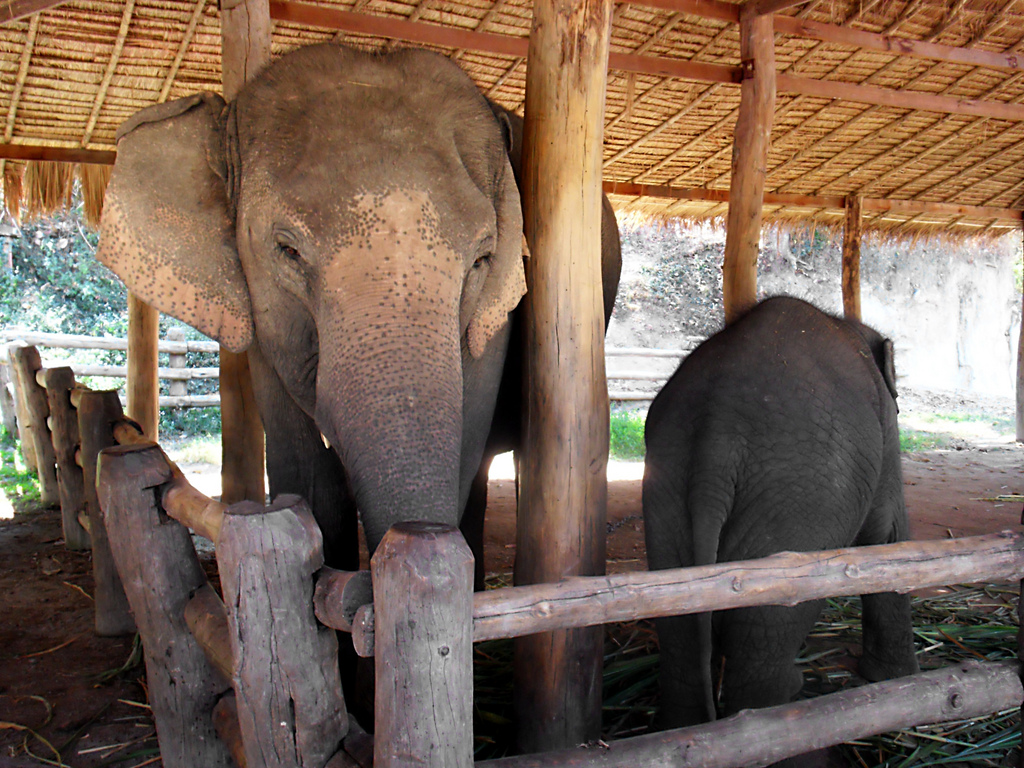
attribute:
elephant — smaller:
[635, 276, 936, 678]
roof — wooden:
[654, 48, 760, 142]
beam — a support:
[87, 277, 167, 422]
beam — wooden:
[681, 67, 887, 256]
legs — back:
[628, 498, 823, 766]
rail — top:
[363, 500, 1020, 634]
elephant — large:
[98, 48, 649, 533]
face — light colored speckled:
[245, 89, 563, 496]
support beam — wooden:
[210, 7, 280, 526]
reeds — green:
[591, 587, 1022, 765]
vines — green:
[15, 225, 130, 390]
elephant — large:
[146, 65, 529, 532]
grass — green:
[611, 410, 640, 458]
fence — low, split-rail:
[2, 327, 1020, 757]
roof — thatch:
[1, 6, 1022, 259]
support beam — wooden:
[514, 14, 630, 760]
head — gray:
[94, 42, 546, 421]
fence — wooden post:
[85, 431, 513, 763]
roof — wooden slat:
[662, 21, 973, 198]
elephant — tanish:
[90, 31, 629, 750]